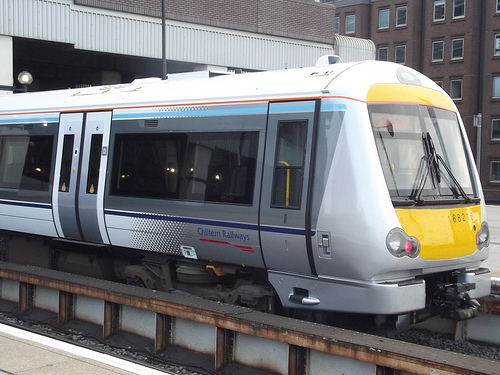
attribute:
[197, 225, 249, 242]
writing — blue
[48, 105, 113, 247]
doors — silver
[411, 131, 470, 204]
windshield wipers — black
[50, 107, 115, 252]
door — white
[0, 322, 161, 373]
line — white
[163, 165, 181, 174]
glare — small